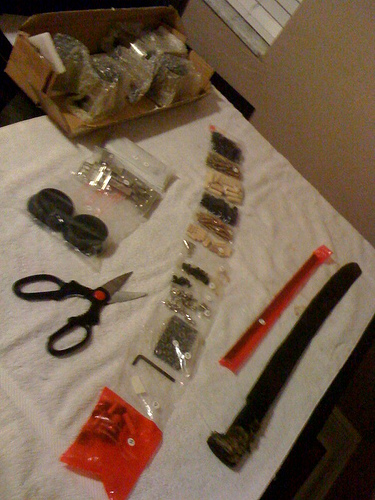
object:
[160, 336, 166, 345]
beads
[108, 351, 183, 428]
plastic bags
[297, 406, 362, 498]
carpet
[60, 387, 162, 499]
packet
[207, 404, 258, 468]
handle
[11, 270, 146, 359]
items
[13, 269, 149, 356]
kitchen scissors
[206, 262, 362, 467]
knife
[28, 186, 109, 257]
sunglasses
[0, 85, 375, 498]
table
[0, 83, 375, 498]
cloth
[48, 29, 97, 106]
items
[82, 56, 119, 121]
baggies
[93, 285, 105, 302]
dot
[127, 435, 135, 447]
number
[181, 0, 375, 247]
floor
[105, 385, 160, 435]
edge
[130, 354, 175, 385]
wrench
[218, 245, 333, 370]
packets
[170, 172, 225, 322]
parts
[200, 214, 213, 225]
pieces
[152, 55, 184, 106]
items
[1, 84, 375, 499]
towel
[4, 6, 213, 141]
box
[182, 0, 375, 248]
wall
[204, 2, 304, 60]
blinds